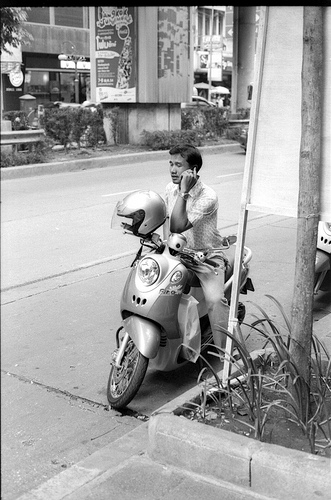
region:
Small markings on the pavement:
[11, 414, 47, 471]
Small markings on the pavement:
[40, 447, 78, 480]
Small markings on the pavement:
[79, 412, 102, 436]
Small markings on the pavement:
[61, 372, 96, 399]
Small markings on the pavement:
[5, 355, 43, 392]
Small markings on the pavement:
[81, 346, 94, 370]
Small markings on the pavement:
[16, 324, 38, 339]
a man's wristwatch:
[177, 191, 191, 200]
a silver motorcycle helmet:
[107, 191, 168, 241]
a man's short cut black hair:
[168, 142, 205, 176]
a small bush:
[43, 103, 99, 146]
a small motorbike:
[104, 235, 258, 409]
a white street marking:
[101, 186, 146, 199]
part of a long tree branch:
[287, 2, 324, 416]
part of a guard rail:
[0, 126, 52, 147]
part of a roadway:
[0, 146, 303, 487]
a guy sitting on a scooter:
[121, 145, 240, 399]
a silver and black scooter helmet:
[109, 187, 165, 239]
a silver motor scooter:
[100, 229, 244, 397]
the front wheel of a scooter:
[106, 326, 142, 399]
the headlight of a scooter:
[130, 254, 170, 295]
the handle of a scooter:
[181, 250, 217, 279]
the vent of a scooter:
[125, 288, 153, 318]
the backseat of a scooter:
[219, 250, 263, 299]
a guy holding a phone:
[182, 169, 201, 186]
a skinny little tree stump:
[290, 110, 323, 221]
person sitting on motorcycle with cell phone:
[91, 133, 261, 415]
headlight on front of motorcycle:
[131, 252, 170, 290]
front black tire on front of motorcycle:
[95, 329, 158, 414]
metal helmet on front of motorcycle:
[101, 184, 170, 242]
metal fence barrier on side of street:
[0, 126, 51, 159]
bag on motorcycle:
[170, 289, 205, 367]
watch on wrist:
[178, 188, 193, 203]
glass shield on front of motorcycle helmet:
[106, 200, 144, 235]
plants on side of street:
[185, 299, 329, 455]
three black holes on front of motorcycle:
[125, 289, 156, 310]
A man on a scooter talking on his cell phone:
[99, 136, 258, 410]